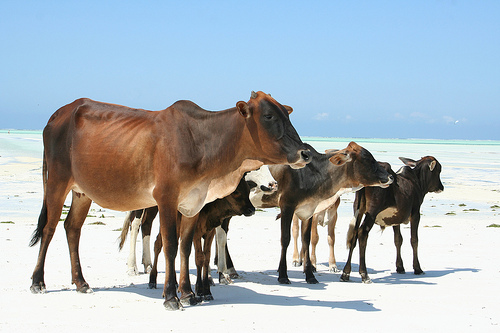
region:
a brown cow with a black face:
[26, 93, 309, 313]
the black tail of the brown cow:
[26, 191, 56, 248]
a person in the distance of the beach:
[0, 116, 19, 145]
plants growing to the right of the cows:
[443, 174, 499, 276]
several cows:
[11, 83, 463, 320]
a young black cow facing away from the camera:
[341, 148, 457, 298]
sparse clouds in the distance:
[301, 97, 475, 138]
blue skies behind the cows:
[23, 15, 464, 82]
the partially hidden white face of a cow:
[226, 143, 281, 205]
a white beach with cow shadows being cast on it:
[1, 215, 488, 331]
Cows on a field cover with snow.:
[18, 75, 452, 306]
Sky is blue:
[7, 2, 498, 100]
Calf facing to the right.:
[341, 152, 453, 280]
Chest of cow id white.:
[177, 157, 258, 218]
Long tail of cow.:
[18, 131, 60, 255]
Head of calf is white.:
[245, 158, 286, 196]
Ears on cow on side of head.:
[224, 91, 305, 123]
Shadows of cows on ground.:
[92, 250, 489, 312]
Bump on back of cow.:
[160, 90, 211, 127]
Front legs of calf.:
[385, 215, 429, 279]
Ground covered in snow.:
[204, 283, 329, 331]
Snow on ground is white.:
[38, 234, 309, 331]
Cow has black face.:
[255, 96, 318, 174]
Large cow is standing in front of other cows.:
[56, 82, 303, 227]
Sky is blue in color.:
[311, 50, 483, 133]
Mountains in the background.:
[306, 102, 493, 136]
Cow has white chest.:
[163, 165, 246, 215]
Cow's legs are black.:
[153, 175, 203, 323]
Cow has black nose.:
[296, 144, 319, 174]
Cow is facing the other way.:
[390, 140, 429, 290]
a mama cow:
[28, 65, 293, 286]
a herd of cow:
[384, 144, 434, 296]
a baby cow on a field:
[370, 140, 445, 300]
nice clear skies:
[280, 50, 435, 101]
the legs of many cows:
[3, 258, 439, 275]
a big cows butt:
[48, 85, 144, 241]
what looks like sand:
[255, 227, 291, 317]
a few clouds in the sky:
[260, 21, 423, 134]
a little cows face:
[255, 177, 276, 213]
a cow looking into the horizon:
[393, 134, 473, 297]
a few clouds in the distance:
[307, 97, 487, 137]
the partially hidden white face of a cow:
[240, 166, 278, 223]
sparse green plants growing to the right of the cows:
[438, 156, 499, 268]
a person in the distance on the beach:
[1, 119, 26, 144]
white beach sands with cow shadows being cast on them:
[17, 251, 470, 331]